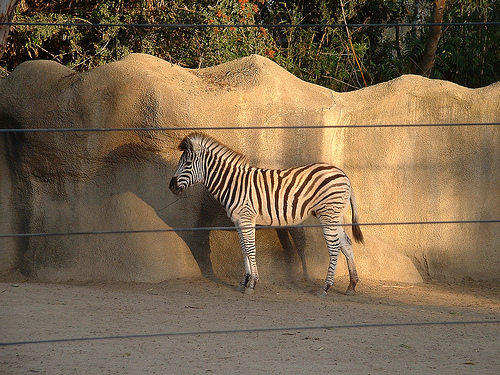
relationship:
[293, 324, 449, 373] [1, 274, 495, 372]
leaves on ground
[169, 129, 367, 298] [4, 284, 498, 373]
zebra standing in dirt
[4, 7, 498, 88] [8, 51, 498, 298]
trees behind wall